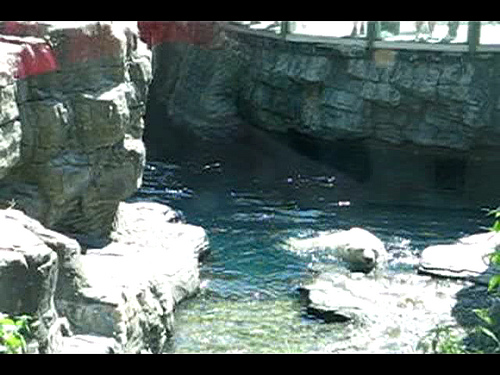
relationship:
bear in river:
[289, 226, 389, 268] [127, 129, 498, 354]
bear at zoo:
[289, 226, 389, 268] [0, 20, 484, 346]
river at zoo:
[127, 129, 498, 354] [0, 20, 484, 346]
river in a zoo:
[127, 129, 498, 354] [0, 20, 484, 346]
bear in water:
[289, 226, 389, 268] [196, 171, 264, 224]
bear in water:
[282, 217, 389, 276] [205, 179, 288, 245]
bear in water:
[289, 226, 389, 268] [214, 177, 297, 267]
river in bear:
[127, 129, 498, 354] [282, 217, 389, 276]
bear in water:
[289, 226, 389, 268] [219, 171, 285, 221]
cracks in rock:
[32, 135, 122, 179] [25, 92, 144, 240]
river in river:
[127, 129, 498, 354] [144, 129, 492, 352]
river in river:
[127, 129, 498, 354] [129, 100, 492, 366]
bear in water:
[289, 226, 389, 268] [134, 94, 494, 350]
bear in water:
[289, 226, 389, 268] [143, 126, 451, 343]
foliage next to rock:
[0, 308, 30, 356] [1, 249, 61, 316]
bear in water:
[289, 226, 389, 268] [189, 290, 308, 350]